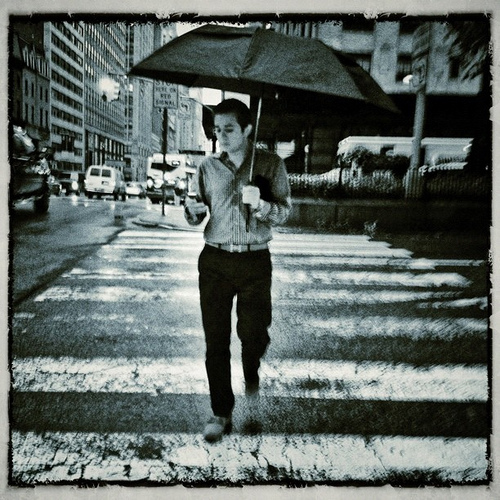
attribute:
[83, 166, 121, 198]
van — white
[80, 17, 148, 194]
buildong — tall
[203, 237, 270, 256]
belt — white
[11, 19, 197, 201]
building — tall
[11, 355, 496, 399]
stripe — white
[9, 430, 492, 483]
stripe — white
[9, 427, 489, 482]
line — white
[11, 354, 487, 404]
line — white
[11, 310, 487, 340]
line — white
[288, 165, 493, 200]
fence — black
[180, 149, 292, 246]
shirt — grey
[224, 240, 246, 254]
buckle — belt